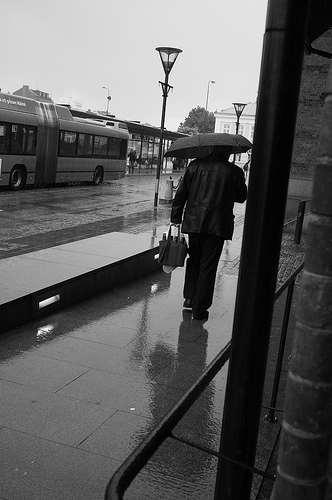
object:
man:
[167, 134, 249, 321]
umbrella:
[159, 132, 253, 159]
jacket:
[168, 150, 247, 240]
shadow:
[144, 318, 222, 490]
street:
[0, 226, 332, 499]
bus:
[2, 91, 131, 193]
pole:
[151, 44, 179, 212]